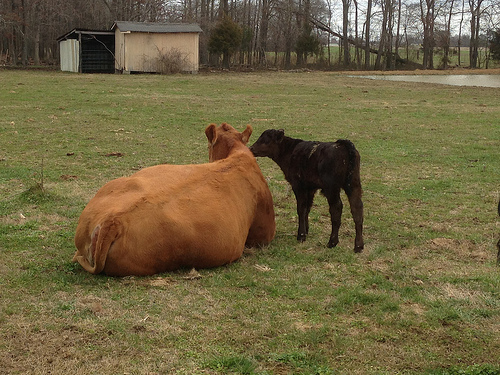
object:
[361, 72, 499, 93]
pond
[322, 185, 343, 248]
leg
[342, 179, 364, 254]
leg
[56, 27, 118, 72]
shed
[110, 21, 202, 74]
building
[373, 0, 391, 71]
trees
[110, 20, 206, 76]
shed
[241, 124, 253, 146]
cow ear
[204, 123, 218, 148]
cow ear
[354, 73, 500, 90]
water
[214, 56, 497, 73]
tree line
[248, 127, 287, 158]
head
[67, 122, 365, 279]
cross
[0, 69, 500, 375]
ground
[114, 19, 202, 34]
grey roof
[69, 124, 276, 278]
cow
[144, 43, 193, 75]
bush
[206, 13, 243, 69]
tree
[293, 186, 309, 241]
leg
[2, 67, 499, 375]
grass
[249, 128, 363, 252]
calf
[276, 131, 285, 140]
ear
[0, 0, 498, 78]
background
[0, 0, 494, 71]
forest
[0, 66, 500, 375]
field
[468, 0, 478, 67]
trees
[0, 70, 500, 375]
yard